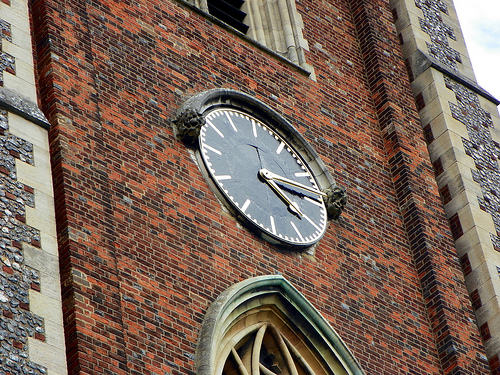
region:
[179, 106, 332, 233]
The clock face is black.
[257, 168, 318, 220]
The hands are gold.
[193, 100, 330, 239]
The dashes are gold.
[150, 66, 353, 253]
The clock is on the building.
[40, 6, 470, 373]
The building is brick.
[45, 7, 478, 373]
The building is black and red.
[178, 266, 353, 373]
THe window is arched.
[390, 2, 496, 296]
The pillar is gray.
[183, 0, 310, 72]
The window is gray.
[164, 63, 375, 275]
The clock is coming out of the building.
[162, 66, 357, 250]
A clock is on the wall of the building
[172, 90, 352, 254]
The clock is painted black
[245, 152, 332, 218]
The hands of the clock are a gold color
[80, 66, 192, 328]
The building is made of red bricks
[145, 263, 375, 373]
A stone archway is on the side of the building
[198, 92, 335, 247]
The clock tells the time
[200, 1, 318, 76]
A window is on the wall of the building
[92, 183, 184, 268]
Bricks make up the wall of the building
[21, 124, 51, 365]
Grey bricks are on the wall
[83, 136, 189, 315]
A variety of bricks make up the wall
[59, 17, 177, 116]
a brick wall of building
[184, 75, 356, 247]
physical clock on a brick wall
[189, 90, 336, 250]
an analog clock on wall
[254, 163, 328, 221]
the hour and minute hands of a clock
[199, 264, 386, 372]
the entrance to a building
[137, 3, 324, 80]
windows of a building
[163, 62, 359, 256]
a circular clock on wall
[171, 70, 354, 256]
a black analog clock on wall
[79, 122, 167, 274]
multi color brick wall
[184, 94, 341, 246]
number hands of a clock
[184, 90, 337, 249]
black and gold clock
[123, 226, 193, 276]
red bricks on building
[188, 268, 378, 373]
an arched window on building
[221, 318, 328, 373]
designed windows on building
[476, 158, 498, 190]
small grey bricks on building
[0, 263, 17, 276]
small red bricks on building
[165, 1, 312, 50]
a window opening above clock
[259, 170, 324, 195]
the big hand on clock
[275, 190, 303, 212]
the small hand on clock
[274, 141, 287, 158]
minutes on the clock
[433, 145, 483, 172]
brick on a building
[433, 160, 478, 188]
brick on a building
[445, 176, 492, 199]
brick on a building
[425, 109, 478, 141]
brick on a building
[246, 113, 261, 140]
time indicator on a clock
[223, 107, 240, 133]
time indicator on a clock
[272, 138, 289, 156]
time indicator on a clock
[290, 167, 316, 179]
time indicator on a clock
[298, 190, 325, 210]
time indicator on a clock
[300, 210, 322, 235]
time indicator on a clock